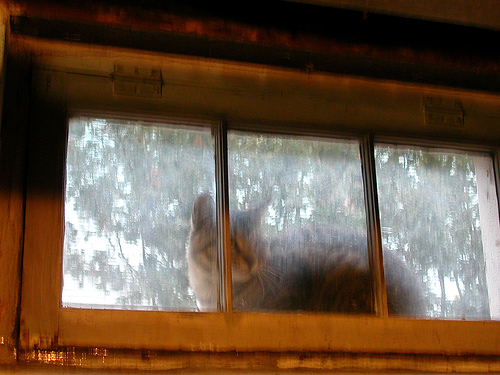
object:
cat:
[183, 189, 427, 321]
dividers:
[212, 119, 237, 311]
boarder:
[160, 23, 415, 101]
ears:
[190, 191, 270, 224]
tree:
[227, 132, 364, 231]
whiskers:
[255, 254, 284, 294]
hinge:
[420, 92, 470, 127]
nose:
[249, 256, 264, 273]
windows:
[66, 104, 475, 319]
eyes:
[188, 234, 281, 245]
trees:
[65, 115, 499, 323]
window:
[63, 109, 222, 314]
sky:
[82, 229, 109, 260]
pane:
[64, 115, 219, 313]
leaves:
[104, 153, 172, 189]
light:
[70, 283, 90, 293]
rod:
[357, 136, 389, 318]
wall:
[9, 218, 82, 365]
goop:
[12, 328, 127, 365]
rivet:
[109, 64, 166, 96]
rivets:
[108, 59, 480, 127]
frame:
[60, 308, 499, 359]